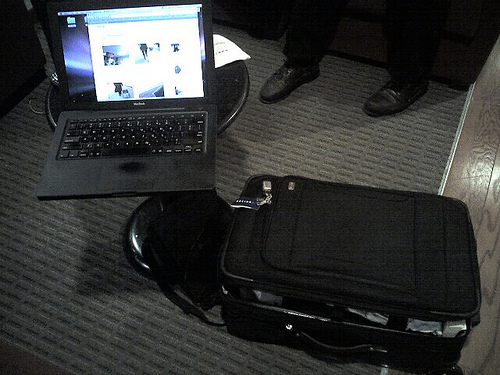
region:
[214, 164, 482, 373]
a black suitcase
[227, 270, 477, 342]
the suitcase is open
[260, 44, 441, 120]
black shoes on the ground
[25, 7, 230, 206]
a laptop on a lap tray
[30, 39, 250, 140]
the lap tray is black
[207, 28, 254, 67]
a white paper on the lap tray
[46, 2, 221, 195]
the lap top is on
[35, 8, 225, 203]
the laptop is black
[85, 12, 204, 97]
a page open on the laptop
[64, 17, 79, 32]
an icon on the laptop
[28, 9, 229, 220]
a laptop on a table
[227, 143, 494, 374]
a luggage bag on the floor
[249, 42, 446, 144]
Black shoes on a person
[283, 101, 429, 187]
Gray carpet on the floor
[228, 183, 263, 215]
A tag on a zipper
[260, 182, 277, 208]
a zipper on a piece of luggage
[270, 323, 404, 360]
a handle on a piece of luggage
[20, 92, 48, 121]
a cord on the floor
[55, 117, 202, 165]
A keyboard on a laptop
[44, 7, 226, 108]
a screen on a laptop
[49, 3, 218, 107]
Laptop screen is turned on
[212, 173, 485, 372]
Black suitcase on the floor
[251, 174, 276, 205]
A lock on the suitcase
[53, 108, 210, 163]
Black keys on laptop keyboard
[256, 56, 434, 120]
A pair of black shoes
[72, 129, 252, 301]
Shadow on the carpet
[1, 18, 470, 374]
Gray carpet on the floor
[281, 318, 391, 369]
Black handle of a bag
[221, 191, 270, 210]
Tags on the suitcase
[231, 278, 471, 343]
Clothes inside the suitcase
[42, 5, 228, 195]
The computer is on.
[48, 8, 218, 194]
The computer is black.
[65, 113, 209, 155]
The keyboard is black.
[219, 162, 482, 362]
The suitcase is black.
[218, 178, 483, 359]
The suitcase is open.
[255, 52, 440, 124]
His shoes are black.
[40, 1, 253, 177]
The computer is on the table.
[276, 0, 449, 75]
His pants are black.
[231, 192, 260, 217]
The tag is silver.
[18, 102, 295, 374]
The carpet is grey.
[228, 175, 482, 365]
suitcase is on the ground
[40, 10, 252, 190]
laptop is on the table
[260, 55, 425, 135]
person is wearing black shoes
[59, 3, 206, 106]
laptop screen is on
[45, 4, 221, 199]
laptop is balck in color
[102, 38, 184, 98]
pictures on the laptop screen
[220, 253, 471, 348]
suitcase is open and on the floor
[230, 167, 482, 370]
suitcase is black in color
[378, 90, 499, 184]
floor has carpet and wood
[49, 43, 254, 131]
table is black in color